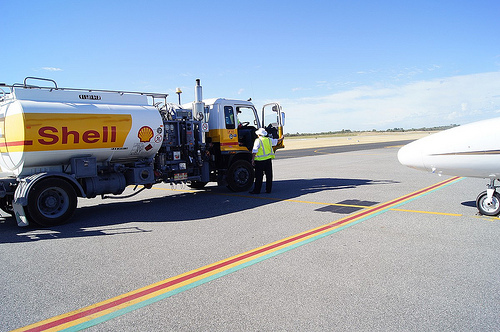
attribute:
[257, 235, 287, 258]
line — red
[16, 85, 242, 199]
truck — yellow, white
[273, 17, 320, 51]
sky — blue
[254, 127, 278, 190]
man — standing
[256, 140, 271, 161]
vest — gray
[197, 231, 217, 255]
ground — gray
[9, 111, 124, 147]
sign — red, shell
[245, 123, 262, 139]
hat — white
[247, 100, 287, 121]
door — open, ope, white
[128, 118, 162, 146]
logo — shell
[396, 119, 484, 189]
plane — white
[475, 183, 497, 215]
wheel — small, black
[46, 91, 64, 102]
top — white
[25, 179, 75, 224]
tire — black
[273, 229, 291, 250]
street — blue